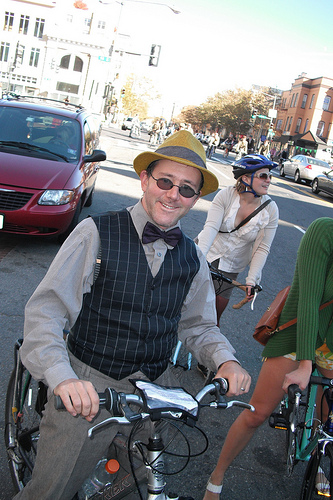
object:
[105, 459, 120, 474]
cap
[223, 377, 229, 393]
handlebar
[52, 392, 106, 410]
handlebar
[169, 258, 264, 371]
bicycle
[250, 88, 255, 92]
light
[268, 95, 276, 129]
pole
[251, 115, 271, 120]
light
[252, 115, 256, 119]
street light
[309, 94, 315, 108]
window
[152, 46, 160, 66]
light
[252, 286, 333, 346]
bag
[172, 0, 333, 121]
sky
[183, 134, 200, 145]
yellow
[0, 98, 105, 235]
maroon car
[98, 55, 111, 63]
sign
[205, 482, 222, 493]
sandle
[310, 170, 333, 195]
car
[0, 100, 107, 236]
car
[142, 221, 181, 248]
black bowtie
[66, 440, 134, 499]
water bottle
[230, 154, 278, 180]
helmet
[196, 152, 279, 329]
woman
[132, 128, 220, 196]
hat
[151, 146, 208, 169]
trim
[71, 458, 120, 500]
bottle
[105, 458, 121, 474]
top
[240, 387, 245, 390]
wedding ring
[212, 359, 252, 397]
man's hand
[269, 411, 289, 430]
pedal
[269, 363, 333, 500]
bike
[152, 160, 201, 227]
face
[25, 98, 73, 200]
van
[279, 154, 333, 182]
car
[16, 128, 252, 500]
man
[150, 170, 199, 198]
sunglasses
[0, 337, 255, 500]
bicycle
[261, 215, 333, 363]
green sweater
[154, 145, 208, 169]
band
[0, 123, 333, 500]
road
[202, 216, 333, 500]
she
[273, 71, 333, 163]
building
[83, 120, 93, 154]
window